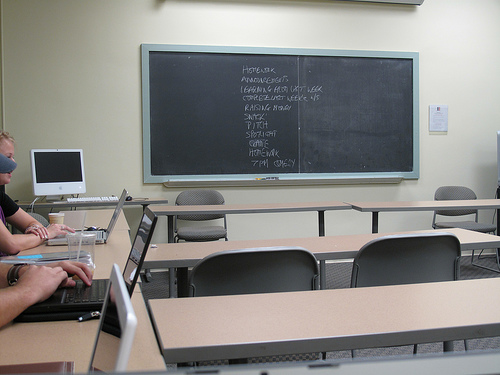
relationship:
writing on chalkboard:
[241, 66, 304, 157] [147, 47, 424, 191]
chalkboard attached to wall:
[147, 47, 424, 191] [14, 7, 499, 188]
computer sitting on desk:
[28, 146, 118, 211] [17, 197, 180, 240]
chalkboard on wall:
[147, 47, 424, 191] [14, 7, 499, 188]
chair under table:
[174, 188, 233, 251] [146, 194, 497, 239]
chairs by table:
[177, 241, 489, 291] [146, 194, 497, 239]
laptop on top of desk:
[35, 202, 124, 244] [32, 199, 123, 362]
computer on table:
[28, 146, 118, 211] [146, 194, 497, 239]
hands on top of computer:
[14, 257, 96, 301] [36, 206, 154, 312]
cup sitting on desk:
[46, 212, 74, 232] [0, 208, 171, 375]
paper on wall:
[430, 105, 449, 132] [14, 7, 499, 188]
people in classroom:
[4, 140, 87, 343] [13, 20, 499, 342]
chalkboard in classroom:
[147, 47, 424, 191] [13, 20, 499, 342]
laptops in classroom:
[13, 191, 149, 360] [13, 20, 499, 342]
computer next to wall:
[28, 146, 118, 211] [14, 7, 499, 188]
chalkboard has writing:
[147, 47, 424, 191] [241, 66, 304, 157]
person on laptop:
[1, 135, 41, 238] [35, 202, 124, 244]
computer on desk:
[28, 146, 118, 211] [17, 197, 180, 240]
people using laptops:
[4, 140, 87, 343] [13, 191, 149, 360]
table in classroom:
[146, 194, 497, 239] [13, 20, 499, 342]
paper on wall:
[431, 103, 453, 135] [14, 7, 499, 188]